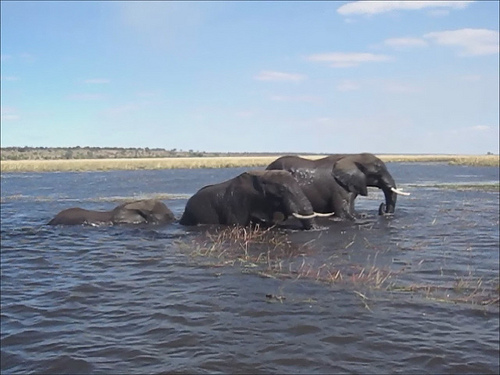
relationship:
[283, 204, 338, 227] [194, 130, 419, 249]
tusk on elephant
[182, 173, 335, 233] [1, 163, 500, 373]
elephant in water